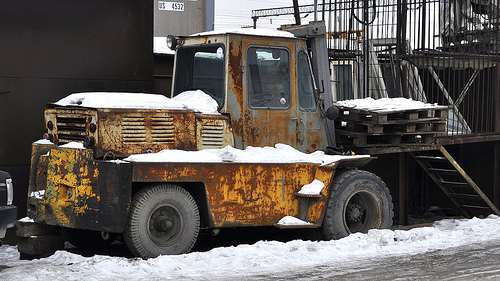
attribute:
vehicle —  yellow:
[56, 31, 343, 262]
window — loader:
[249, 45, 293, 112]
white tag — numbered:
[158, 1, 188, 11]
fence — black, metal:
[314, 0, 499, 133]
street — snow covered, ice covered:
[104, 196, 499, 256]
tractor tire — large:
[123, 180, 202, 260]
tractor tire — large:
[322, 165, 397, 240]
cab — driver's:
[172, 28, 328, 153]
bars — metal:
[313, 0, 496, 134]